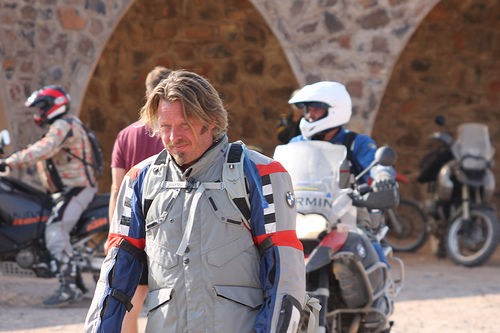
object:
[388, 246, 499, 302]
shadow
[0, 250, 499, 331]
ground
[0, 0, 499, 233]
structure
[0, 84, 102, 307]
man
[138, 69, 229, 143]
hair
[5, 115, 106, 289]
outfit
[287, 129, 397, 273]
outfit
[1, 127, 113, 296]
bike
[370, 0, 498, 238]
wall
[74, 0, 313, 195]
wall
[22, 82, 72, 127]
helmet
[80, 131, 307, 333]
jacket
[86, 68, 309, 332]
man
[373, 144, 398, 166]
mirror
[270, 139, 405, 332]
motorcycle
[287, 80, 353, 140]
helmet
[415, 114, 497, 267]
motorbike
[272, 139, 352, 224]
windshield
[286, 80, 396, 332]
man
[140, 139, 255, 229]
shoulder straps